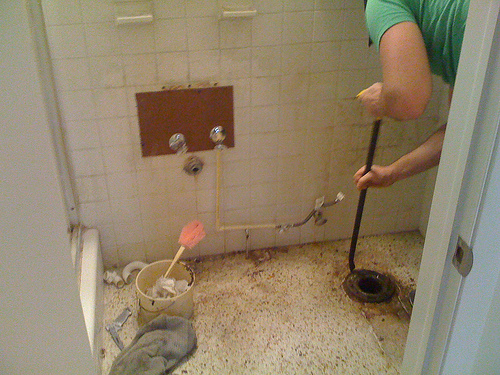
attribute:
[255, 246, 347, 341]
floor — brown and white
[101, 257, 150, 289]
pipes — white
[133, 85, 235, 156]
square — brown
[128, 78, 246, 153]
panel — brown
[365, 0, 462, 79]
shirt —  green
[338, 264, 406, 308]
drain — brown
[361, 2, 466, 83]
tee shirt — green, short sleeved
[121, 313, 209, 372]
towel —  grey 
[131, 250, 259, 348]
bucket —  white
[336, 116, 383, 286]
metal pole — long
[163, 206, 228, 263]
toilet brush — pink and white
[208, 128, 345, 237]
pipe — white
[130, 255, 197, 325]
bucket — white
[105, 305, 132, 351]
knife — opened